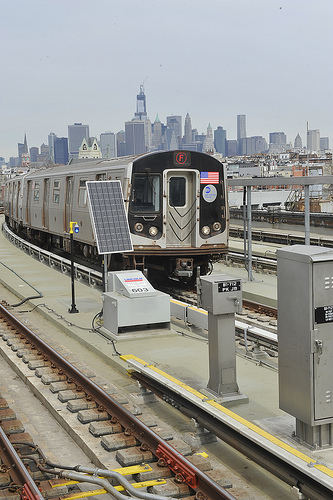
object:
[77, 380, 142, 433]
railroad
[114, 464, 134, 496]
railroad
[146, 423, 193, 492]
railroad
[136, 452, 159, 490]
railroad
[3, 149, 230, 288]
commuter train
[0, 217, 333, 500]
tracks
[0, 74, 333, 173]
large city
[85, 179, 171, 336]
solar panel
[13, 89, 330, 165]
cityscape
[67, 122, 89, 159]
tall buildings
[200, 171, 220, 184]
american flag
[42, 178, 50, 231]
doors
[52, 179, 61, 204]
windows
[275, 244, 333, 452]
electrical box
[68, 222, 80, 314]
thin pole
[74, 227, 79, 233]
blue light